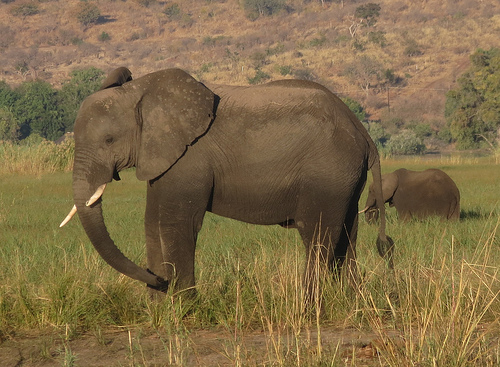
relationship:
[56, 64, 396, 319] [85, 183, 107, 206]
elephant has tusk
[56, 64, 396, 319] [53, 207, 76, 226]
elephant has tusk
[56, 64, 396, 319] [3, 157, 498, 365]
elephant on top grass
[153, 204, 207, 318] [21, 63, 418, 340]
front leg of elephant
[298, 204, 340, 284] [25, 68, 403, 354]
back leg of elephant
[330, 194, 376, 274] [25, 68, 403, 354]
back leg of elephant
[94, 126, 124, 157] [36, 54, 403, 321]
eye of an elephant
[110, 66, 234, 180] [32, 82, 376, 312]
ear of an elephant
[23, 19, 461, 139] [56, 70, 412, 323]
desert on back side of elephant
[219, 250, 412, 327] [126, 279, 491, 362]
grass present on ground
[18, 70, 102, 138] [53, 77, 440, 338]
trees on backside of elephant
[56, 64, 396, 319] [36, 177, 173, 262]
elephant standing in field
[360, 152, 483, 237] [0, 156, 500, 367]
elephant standing in field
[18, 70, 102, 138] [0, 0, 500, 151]
trees at bottom of a hill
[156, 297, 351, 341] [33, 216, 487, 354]
dirt in field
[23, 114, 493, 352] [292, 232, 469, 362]
field of grass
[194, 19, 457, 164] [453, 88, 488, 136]
hill covered in shrubs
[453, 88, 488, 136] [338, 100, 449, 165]
shrubs and bushes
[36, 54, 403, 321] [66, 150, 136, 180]
elephant has jaws